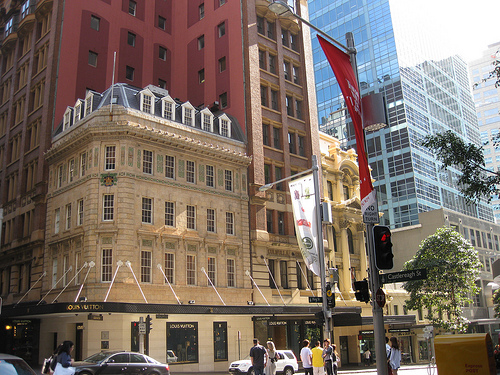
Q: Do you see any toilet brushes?
A: No, there are no toilet brushes.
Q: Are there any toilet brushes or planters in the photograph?
A: No, there are no toilet brushes or planters.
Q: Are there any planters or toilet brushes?
A: No, there are no toilet brushes or planters.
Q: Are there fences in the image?
A: No, there are no fences.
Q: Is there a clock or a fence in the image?
A: No, there are no fences or clocks.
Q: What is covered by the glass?
A: The building is covered by the glass.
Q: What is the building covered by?
A: The building is covered by the glass.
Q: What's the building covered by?
A: The building is covered by the glass.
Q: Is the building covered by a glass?
A: Yes, the building is covered by a glass.